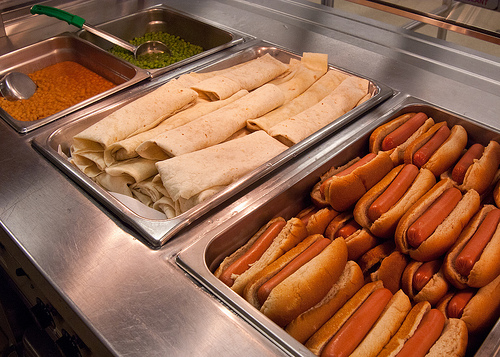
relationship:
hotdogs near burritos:
[202, 115, 500, 351] [68, 50, 377, 220]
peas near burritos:
[83, 10, 222, 67] [68, 50, 377, 220]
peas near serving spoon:
[83, 10, 222, 67] [28, 3, 172, 61]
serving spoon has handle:
[28, 3, 172, 61] [27, 3, 86, 27]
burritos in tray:
[68, 50, 377, 220] [31, 40, 395, 248]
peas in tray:
[100, 29, 206, 69] [76, 1, 244, 81]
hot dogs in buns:
[209, 107, 499, 355] [215, 106, 497, 355]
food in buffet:
[70, 50, 377, 219] [1, 0, 499, 353]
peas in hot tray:
[104, 27, 206, 70] [78, 2, 242, 77]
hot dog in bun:
[221, 219, 283, 283] [214, 215, 303, 292]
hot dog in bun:
[256, 236, 329, 300] [241, 230, 347, 322]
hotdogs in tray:
[202, 115, 500, 351] [178, 95, 498, 355]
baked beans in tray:
[0, 58, 117, 119] [1, 30, 151, 135]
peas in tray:
[111, 30, 204, 70] [76, 1, 244, 81]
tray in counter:
[1, 30, 151, 135] [0, 0, 497, 354]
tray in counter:
[76, 1, 244, 81] [0, 0, 497, 354]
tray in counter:
[31, 40, 395, 248] [0, 0, 497, 354]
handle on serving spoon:
[27, 3, 86, 27] [28, 3, 172, 61]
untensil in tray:
[30, 1, 170, 59] [76, 1, 244, 81]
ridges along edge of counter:
[220, 0, 499, 100] [0, 0, 497, 354]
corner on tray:
[135, 214, 180, 247] [31, 40, 395, 248]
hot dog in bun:
[396, 306, 444, 355] [375, 300, 470, 355]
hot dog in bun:
[322, 286, 392, 355] [305, 277, 410, 355]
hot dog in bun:
[405, 184, 462, 246] [395, 175, 482, 258]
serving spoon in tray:
[28, 3, 172, 61] [76, 1, 244, 81]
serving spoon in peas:
[28, 3, 172, 61] [103, 30, 208, 72]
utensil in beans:
[1, 59, 119, 119] [2, 59, 122, 120]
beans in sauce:
[2, 59, 122, 120] [0, 59, 118, 119]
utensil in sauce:
[1, 59, 119, 119] [0, 59, 118, 119]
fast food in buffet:
[0, 30, 499, 354] [1, 0, 499, 353]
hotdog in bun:
[367, 162, 417, 217] [354, 161, 435, 233]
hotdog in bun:
[380, 109, 428, 149] [370, 110, 432, 161]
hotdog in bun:
[414, 124, 451, 163] [404, 118, 467, 173]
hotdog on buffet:
[367, 162, 417, 217] [1, 0, 499, 353]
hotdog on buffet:
[380, 109, 428, 149] [1, 0, 499, 353]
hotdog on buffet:
[414, 124, 451, 163] [1, 0, 499, 353]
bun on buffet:
[354, 161, 435, 233] [1, 0, 499, 353]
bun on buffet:
[370, 110, 432, 161] [1, 0, 499, 353]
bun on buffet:
[404, 118, 467, 173] [1, 0, 499, 353]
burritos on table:
[68, 50, 377, 220] [1, 1, 461, 352]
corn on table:
[33, 71, 102, 100] [1, 1, 461, 352]